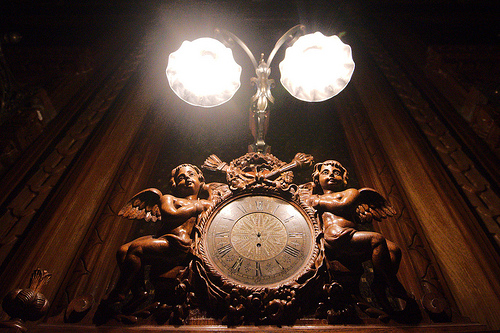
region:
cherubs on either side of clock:
[110, 145, 416, 315]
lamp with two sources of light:
[151, 20, 381, 115]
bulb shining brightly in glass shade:
[141, 21, 246, 121]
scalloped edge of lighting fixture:
[270, 25, 360, 110]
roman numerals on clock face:
[181, 177, 331, 307]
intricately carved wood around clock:
[85, 135, 445, 317]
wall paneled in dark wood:
[46, 60, 451, 291]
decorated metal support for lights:
[191, 25, 301, 162]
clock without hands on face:
[200, 180, 325, 300]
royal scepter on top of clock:
[226, 145, 317, 192]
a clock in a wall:
[198, 190, 320, 287]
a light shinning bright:
[278, 25, 358, 105]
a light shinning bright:
[164, 24, 239, 114]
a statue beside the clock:
[308, 147, 422, 314]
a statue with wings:
[111, 153, 203, 302]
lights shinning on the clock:
[135, 5, 360, 117]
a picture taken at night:
[2, 1, 499, 331]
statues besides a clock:
[113, 150, 406, 315]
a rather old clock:
[205, 185, 320, 296]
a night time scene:
[0, 0, 499, 327]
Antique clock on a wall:
[104, 142, 446, 329]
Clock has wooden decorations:
[110, 140, 431, 324]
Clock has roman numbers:
[204, 185, 321, 292]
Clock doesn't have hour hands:
[187, 177, 327, 307]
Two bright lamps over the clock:
[157, 10, 358, 158]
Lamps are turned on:
[152, 27, 362, 125]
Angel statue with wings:
[282, 152, 412, 304]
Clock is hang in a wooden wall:
[0, 7, 490, 331]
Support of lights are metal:
[225, 18, 293, 156]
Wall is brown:
[11, 7, 496, 328]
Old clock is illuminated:
[111, 132, 407, 328]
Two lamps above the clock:
[156, 7, 362, 157]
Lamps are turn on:
[159, 31, 357, 112]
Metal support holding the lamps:
[235, 26, 278, 156]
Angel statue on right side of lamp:
[308, 144, 417, 301]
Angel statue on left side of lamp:
[108, 153, 212, 308]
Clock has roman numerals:
[197, 185, 322, 290]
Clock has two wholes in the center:
[250, 215, 262, 247]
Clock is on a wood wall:
[2, 0, 493, 322]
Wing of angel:
[351, 183, 405, 223]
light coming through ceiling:
[187, 59, 246, 87]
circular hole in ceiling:
[278, 31, 375, 111]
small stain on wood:
[410, 172, 450, 242]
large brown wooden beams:
[373, 72, 499, 309]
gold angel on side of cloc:
[314, 159, 410, 283]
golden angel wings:
[115, 184, 180, 219]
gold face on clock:
[207, 194, 324, 287]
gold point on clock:
[257, 51, 276, 143]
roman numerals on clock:
[212, 216, 246, 277]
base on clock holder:
[97, 312, 193, 332]